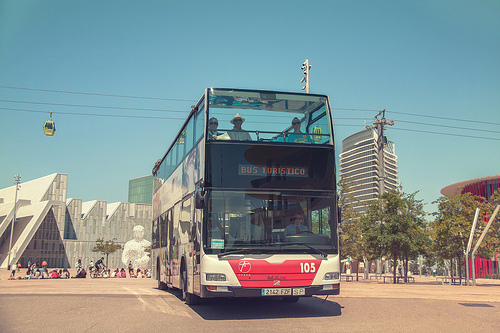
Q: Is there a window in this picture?
A: Yes, there is a window.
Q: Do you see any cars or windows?
A: Yes, there is a window.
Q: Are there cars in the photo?
A: No, there are no cars.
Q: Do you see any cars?
A: No, there are no cars.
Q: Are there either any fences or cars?
A: No, there are no cars or fences.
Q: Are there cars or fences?
A: No, there are no cars or fences.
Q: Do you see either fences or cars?
A: No, there are no cars or fences.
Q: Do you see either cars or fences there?
A: No, there are no cars or fences.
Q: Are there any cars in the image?
A: No, there are no cars.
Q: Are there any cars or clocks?
A: No, there are no cars or clocks.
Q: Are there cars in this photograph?
A: No, there are no cars.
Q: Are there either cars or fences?
A: No, there are no cars or fences.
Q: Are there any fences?
A: No, there are no fences.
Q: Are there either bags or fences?
A: No, there are no fences or bags.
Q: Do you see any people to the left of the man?
A: Yes, there is a person to the left of the man.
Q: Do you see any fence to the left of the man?
A: No, there is a person to the left of the man.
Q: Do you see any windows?
A: Yes, there is a window.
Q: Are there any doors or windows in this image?
A: Yes, there is a window.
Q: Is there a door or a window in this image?
A: Yes, there is a window.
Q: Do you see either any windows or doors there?
A: Yes, there is a window.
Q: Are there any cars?
A: No, there are no cars.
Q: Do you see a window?
A: Yes, there is a window.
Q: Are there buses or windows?
A: Yes, there is a window.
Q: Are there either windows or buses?
A: Yes, there is a window.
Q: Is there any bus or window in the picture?
A: Yes, there is a window.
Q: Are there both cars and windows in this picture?
A: No, there is a window but no cars.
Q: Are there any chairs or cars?
A: No, there are no cars or chairs.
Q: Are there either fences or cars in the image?
A: No, there are no cars or fences.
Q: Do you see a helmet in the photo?
A: No, there are no helmets.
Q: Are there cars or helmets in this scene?
A: No, there are no helmets or cars.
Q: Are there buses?
A: Yes, there is a bus.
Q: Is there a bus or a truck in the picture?
A: Yes, there is a bus.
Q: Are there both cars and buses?
A: No, there is a bus but no cars.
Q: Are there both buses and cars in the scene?
A: No, there is a bus but no cars.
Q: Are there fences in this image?
A: No, there are no fences.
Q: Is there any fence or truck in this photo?
A: No, there are no fences or trucks.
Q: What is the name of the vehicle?
A: The vehicle is a bus.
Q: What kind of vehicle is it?
A: The vehicle is a bus.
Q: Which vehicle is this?
A: This is a bus.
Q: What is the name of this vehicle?
A: This is a bus.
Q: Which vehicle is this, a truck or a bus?
A: This is a bus.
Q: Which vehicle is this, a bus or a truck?
A: This is a bus.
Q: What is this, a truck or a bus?
A: This is a bus.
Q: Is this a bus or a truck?
A: This is a bus.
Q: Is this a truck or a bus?
A: This is a bus.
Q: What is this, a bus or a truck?
A: This is a bus.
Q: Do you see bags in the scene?
A: No, there are no bags.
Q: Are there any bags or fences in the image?
A: No, there are no bags or fences.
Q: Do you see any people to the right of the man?
A: Yes, there is a person to the right of the man.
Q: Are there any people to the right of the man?
A: Yes, there is a person to the right of the man.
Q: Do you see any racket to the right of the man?
A: No, there is a person to the right of the man.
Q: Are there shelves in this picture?
A: No, there are no shelves.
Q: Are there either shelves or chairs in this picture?
A: No, there are no shelves or chairs.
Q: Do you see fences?
A: No, there are no fences.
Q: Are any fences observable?
A: No, there are no fences.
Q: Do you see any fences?
A: No, there are no fences.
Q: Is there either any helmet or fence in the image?
A: No, there are no fences or helmets.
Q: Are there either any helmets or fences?
A: No, there are no fences or helmets.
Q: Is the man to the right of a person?
A: No, the man is to the left of a person.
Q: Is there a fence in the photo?
A: No, there are no fences.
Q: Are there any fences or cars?
A: No, there are no fences or cars.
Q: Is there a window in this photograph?
A: Yes, there is a window.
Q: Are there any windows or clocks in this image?
A: Yes, there is a window.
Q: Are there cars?
A: No, there are no cars.